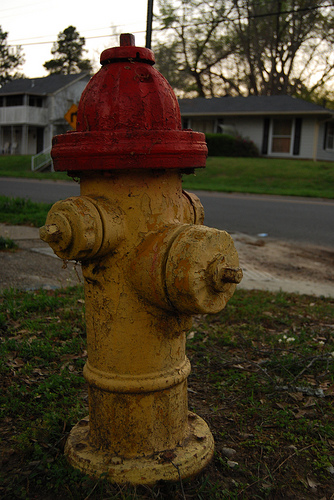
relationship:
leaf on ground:
[276, 397, 297, 412] [0, 196, 332, 499]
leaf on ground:
[11, 355, 28, 376] [0, 196, 332, 499]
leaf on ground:
[232, 360, 245, 371] [0, 196, 332, 499]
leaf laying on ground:
[315, 333, 333, 348] [0, 196, 332, 499]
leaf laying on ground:
[304, 474, 321, 490] [0, 196, 332, 499]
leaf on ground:
[315, 333, 333, 348] [0, 196, 332, 499]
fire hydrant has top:
[37, 30, 242, 490] [43, 27, 208, 170]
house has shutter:
[165, 94, 333, 173] [259, 112, 274, 155]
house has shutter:
[165, 94, 333, 173] [290, 115, 303, 157]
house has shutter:
[165, 94, 333, 173] [182, 116, 193, 132]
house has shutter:
[165, 94, 333, 173] [212, 115, 223, 137]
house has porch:
[2, 73, 97, 169] [2, 94, 47, 127]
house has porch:
[2, 73, 97, 169] [2, 124, 46, 160]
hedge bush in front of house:
[202, 132, 260, 160] [165, 94, 333, 173]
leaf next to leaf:
[276, 397, 297, 412] [304, 474, 321, 490]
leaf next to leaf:
[232, 360, 245, 371] [11, 355, 28, 376]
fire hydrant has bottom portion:
[37, 30, 242, 490] [38, 172, 243, 482]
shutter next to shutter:
[259, 112, 274, 155] [290, 115, 303, 157]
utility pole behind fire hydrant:
[143, 2, 156, 52] [37, 30, 242, 490]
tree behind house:
[148, 2, 247, 98] [165, 94, 333, 173]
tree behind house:
[224, 2, 333, 109] [165, 94, 333, 173]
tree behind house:
[46, 26, 96, 81] [2, 73, 97, 169]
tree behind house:
[1, 26, 23, 84] [2, 73, 97, 169]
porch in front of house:
[2, 94, 47, 127] [2, 73, 97, 169]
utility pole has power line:
[143, 2, 156, 52] [4, 4, 333, 53]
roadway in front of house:
[3, 177, 333, 252] [165, 94, 333, 173]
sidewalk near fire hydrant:
[1, 221, 330, 306] [37, 30, 242, 490]